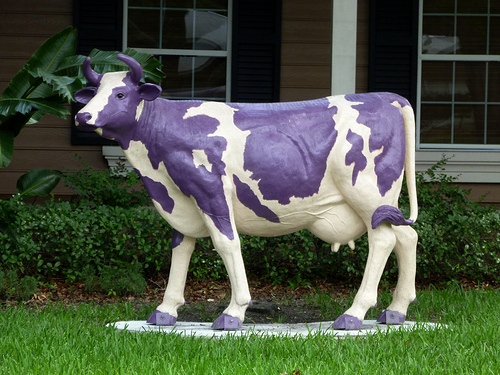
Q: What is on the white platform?
A: Cow.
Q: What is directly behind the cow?
A: Bushes.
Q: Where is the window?
A: The house.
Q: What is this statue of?
A: A cow.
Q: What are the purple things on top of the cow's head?
A: Horns.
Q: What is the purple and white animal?
A: Cow.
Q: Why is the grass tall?
A: It needs mowed.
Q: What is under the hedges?
A: Mulch.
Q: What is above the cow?
A: Green window shutter sets.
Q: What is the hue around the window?
A: Window trim is white.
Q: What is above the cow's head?
A: Large green leaves on plant.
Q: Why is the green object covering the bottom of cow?
A: The grass is long.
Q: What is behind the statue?
A: A building is behind the cow.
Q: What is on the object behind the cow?
A: Windows are on the building.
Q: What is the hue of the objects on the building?
A: The windows are white.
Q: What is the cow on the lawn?
A: A purple and white statue.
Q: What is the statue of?
A: A cow.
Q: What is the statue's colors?
A: Purple and white.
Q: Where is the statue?
A: In front of a house.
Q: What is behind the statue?
A: A house.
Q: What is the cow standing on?
A: Concrete.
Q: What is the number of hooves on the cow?
A: 4.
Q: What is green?
A: Grass.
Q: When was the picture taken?
A: Daytime.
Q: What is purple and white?
A: Cow.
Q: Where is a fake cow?
A: Outside a house.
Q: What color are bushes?
A: Green.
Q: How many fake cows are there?
A: One.